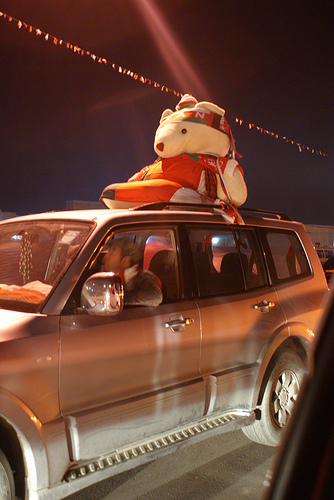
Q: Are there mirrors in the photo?
A: Yes, there is a mirror.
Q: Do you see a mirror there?
A: Yes, there is a mirror.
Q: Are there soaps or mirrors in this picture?
A: Yes, there is a mirror.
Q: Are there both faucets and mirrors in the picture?
A: No, there is a mirror but no faucets.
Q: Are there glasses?
A: No, there are no glasses.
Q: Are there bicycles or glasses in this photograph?
A: No, there are no glasses or bicycles.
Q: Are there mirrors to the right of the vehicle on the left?
A: Yes, there is a mirror to the right of the vehicle.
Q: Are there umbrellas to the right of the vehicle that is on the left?
A: No, there is a mirror to the right of the vehicle.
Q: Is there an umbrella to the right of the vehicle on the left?
A: No, there is a mirror to the right of the vehicle.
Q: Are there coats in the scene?
A: Yes, there is a coat.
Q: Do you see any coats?
A: Yes, there is a coat.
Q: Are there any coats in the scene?
A: Yes, there is a coat.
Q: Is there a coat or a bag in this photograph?
A: Yes, there is a coat.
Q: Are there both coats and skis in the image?
A: No, there is a coat but no skis.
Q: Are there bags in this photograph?
A: No, there are no bags.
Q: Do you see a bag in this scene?
A: No, there are no bags.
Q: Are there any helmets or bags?
A: No, there are no bags or helmets.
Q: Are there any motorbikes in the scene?
A: No, there are no motorbikes.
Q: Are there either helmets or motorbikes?
A: No, there are no motorbikes or helmets.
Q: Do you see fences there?
A: No, there are no fences.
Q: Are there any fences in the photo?
A: No, there are no fences.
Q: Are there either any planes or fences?
A: No, there are no fences or planes.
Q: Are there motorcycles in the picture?
A: No, there are no motorcycles.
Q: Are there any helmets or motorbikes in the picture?
A: No, there are no motorbikes or helmets.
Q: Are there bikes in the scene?
A: No, there are no bikes.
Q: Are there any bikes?
A: No, there are no bikes.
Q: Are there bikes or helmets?
A: No, there are no bikes or helmets.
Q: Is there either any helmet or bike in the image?
A: No, there are no bikes or helmets.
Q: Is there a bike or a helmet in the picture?
A: No, there are no bikes or helmets.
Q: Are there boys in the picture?
A: No, there are no boys.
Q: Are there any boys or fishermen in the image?
A: No, there are no boys or fishermen.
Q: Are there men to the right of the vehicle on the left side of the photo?
A: Yes, there is a man to the right of the vehicle.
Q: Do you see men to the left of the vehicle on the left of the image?
A: No, the man is to the right of the vehicle.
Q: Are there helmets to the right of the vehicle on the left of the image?
A: No, there is a man to the right of the vehicle.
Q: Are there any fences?
A: No, there are no fences.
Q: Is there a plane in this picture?
A: No, there are no airplanes.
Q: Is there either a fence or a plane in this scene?
A: No, there are no airplanes or fences.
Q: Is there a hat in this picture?
A: Yes, there is a hat.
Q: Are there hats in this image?
A: Yes, there is a hat.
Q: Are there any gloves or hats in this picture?
A: Yes, there is a hat.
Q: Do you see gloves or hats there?
A: Yes, there is a hat.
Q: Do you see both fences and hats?
A: No, there is a hat but no fences.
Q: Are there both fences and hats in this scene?
A: No, there is a hat but no fences.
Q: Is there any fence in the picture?
A: No, there are no fences.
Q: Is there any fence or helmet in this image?
A: No, there are no fences or helmets.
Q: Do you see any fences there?
A: No, there are no fences.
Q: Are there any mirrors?
A: Yes, there is a mirror.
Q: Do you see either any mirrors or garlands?
A: Yes, there is a mirror.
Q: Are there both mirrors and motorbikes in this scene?
A: No, there is a mirror but no motorcycles.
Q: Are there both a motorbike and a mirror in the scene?
A: No, there is a mirror but no motorcycles.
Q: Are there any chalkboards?
A: No, there are no chalkboards.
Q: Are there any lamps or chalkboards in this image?
A: No, there are no chalkboards or lamps.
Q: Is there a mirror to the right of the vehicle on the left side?
A: Yes, there is a mirror to the right of the vehicle.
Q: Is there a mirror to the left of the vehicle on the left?
A: No, the mirror is to the right of the vehicle.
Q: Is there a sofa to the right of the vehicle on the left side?
A: No, there is a mirror to the right of the vehicle.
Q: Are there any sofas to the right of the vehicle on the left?
A: No, there is a mirror to the right of the vehicle.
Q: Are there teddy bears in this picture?
A: Yes, there is a teddy bear.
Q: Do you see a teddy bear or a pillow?
A: Yes, there is a teddy bear.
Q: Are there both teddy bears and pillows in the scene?
A: No, there is a teddy bear but no pillows.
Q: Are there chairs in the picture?
A: No, there are no chairs.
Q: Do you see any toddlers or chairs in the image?
A: No, there are no chairs or toddlers.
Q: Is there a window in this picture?
A: Yes, there is a window.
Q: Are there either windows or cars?
A: Yes, there is a window.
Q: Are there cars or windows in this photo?
A: Yes, there is a window.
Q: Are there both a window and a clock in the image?
A: No, there is a window but no clocks.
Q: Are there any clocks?
A: No, there are no clocks.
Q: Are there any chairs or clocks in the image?
A: No, there are no clocks or chairs.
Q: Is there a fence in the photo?
A: No, there are no fences.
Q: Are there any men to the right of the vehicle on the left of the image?
A: Yes, there is a man to the right of the vehicle.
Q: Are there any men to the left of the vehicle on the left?
A: No, the man is to the right of the vehicle.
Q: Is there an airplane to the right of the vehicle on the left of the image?
A: No, there is a man to the right of the vehicle.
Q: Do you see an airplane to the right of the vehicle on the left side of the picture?
A: No, there is a man to the right of the vehicle.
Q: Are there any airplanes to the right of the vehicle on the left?
A: No, there is a man to the right of the vehicle.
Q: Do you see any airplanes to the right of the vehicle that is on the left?
A: No, there is a man to the right of the vehicle.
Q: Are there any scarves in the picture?
A: Yes, there is a scarf.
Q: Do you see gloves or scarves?
A: Yes, there is a scarf.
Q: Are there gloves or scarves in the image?
A: Yes, there is a scarf.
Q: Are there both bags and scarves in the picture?
A: No, there is a scarf but no bags.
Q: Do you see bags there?
A: No, there are no bags.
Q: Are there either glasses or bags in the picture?
A: No, there are no bags or glasses.